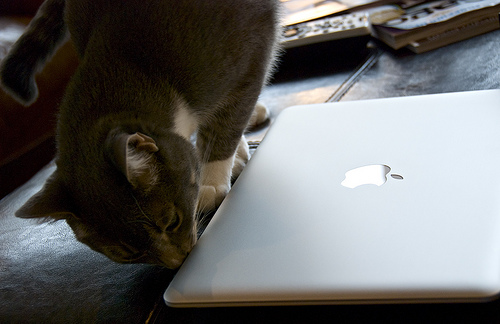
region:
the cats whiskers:
[194, 205, 211, 227]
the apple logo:
[339, 162, 401, 201]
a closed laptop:
[285, 109, 494, 271]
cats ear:
[117, 140, 167, 181]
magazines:
[389, 15, 499, 44]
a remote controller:
[285, 18, 371, 42]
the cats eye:
[160, 218, 184, 233]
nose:
[163, 255, 183, 268]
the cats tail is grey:
[6, 42, 37, 98]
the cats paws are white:
[200, 165, 227, 200]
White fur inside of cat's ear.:
[127, 151, 168, 185]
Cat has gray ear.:
[17, 181, 91, 220]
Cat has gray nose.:
[147, 251, 185, 271]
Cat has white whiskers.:
[177, 201, 214, 221]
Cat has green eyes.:
[156, 210, 182, 230]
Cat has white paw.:
[205, 165, 244, 223]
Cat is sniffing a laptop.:
[134, 166, 230, 285]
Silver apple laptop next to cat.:
[207, 115, 367, 255]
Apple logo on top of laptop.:
[341, 140, 391, 191]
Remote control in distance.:
[290, 13, 439, 65]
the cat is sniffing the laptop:
[26, 12, 290, 319]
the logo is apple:
[336, 140, 416, 220]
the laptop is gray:
[280, 64, 382, 321]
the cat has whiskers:
[11, 28, 241, 305]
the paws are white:
[188, 120, 295, 237]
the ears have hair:
[13, 99, 175, 206]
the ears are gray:
[13, 105, 170, 282]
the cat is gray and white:
[34, 18, 351, 318]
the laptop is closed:
[264, 78, 416, 313]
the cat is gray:
[28, 63, 285, 319]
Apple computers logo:
[338, 160, 403, 190]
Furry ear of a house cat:
[119, 132, 164, 190]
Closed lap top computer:
[156, 86, 498, 306]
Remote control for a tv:
[275, 8, 374, 51]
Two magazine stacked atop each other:
[366, 0, 498, 57]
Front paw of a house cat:
[195, 154, 235, 206]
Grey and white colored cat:
[0, 0, 284, 270]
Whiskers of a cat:
[192, 142, 212, 232]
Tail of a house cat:
[0, 0, 71, 107]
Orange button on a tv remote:
[282, 23, 298, 40]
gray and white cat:
[9, 1, 289, 300]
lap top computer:
[165, 90, 496, 307]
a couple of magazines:
[382, 0, 495, 55]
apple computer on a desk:
[160, 98, 495, 321]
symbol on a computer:
[325, 146, 406, 213]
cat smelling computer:
[10, 130, 208, 281]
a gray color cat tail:
[0, 1, 73, 117]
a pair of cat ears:
[15, 128, 180, 230]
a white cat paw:
[191, 140, 241, 212]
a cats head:
[7, 128, 217, 283]